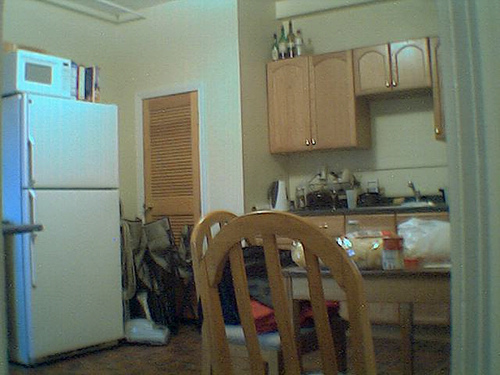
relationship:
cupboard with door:
[266, 47, 370, 155] [264, 54, 314, 156]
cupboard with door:
[266, 47, 370, 155] [309, 47, 359, 152]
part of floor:
[150, 347, 179, 367] [9, 315, 450, 374]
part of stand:
[399, 297, 419, 347] [369, 280, 452, 371]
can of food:
[381, 230, 405, 271] [381, 237, 406, 271]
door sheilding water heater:
[135, 92, 206, 235] [145, 93, 192, 226]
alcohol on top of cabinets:
[268, 20, 313, 64] [267, 36, 445, 159]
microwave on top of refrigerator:
[4, 47, 76, 99] [0, 90, 134, 369]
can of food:
[374, 230, 408, 267] [378, 235, 408, 274]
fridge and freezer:
[1, 90, 124, 370] [19, 96, 124, 187]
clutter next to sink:
[276, 167, 366, 214] [379, 182, 441, 213]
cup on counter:
[346, 187, 358, 212] [218, 163, 491, 323]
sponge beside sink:
[382, 179, 423, 246] [364, 178, 453, 230]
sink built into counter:
[395, 199, 439, 206] [283, 202, 448, 214]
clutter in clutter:
[297, 167, 383, 210] [297, 167, 383, 210]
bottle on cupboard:
[266, 20, 311, 59] [268, 36, 448, 154]